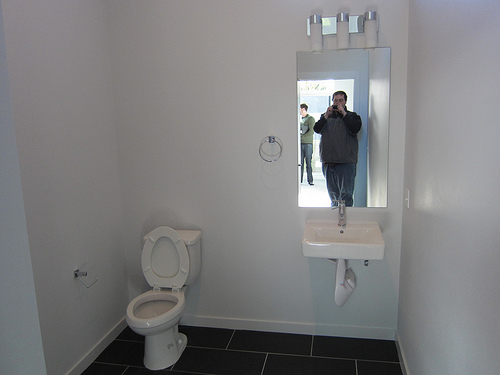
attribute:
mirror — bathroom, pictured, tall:
[290, 43, 393, 210]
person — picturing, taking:
[313, 89, 365, 209]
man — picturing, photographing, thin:
[315, 89, 356, 207]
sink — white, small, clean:
[302, 220, 387, 273]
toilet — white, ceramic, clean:
[125, 224, 205, 374]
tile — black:
[66, 315, 409, 373]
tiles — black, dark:
[58, 317, 402, 374]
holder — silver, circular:
[257, 138, 288, 162]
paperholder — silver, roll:
[74, 269, 95, 289]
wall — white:
[396, 1, 499, 374]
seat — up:
[139, 227, 192, 292]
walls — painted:
[1, 2, 497, 342]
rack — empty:
[256, 137, 282, 163]